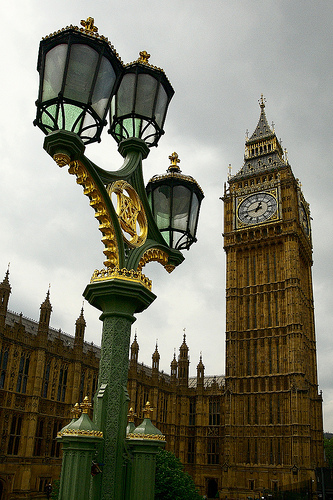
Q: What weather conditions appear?
A: It is overcast.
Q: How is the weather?
A: It is overcast.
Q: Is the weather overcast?
A: Yes, it is overcast.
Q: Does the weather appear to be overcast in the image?
A: Yes, it is overcast.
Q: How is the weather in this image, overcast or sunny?
A: It is overcast.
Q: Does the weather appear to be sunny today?
A: No, it is overcast.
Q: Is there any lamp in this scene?
A: Yes, there is a lamp.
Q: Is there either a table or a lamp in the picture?
A: Yes, there is a lamp.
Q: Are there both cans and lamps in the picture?
A: No, there is a lamp but no cans.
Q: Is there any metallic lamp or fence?
A: Yes, there is a metal lamp.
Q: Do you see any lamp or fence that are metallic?
A: Yes, the lamp is metallic.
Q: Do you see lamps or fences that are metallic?
A: Yes, the lamp is metallic.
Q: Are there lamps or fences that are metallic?
A: Yes, the lamp is metallic.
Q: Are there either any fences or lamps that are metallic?
A: Yes, the lamp is metallic.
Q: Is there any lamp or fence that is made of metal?
A: Yes, the lamp is made of metal.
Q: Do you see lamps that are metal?
A: Yes, there is a metal lamp.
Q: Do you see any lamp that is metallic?
A: Yes, there is a lamp that is metallic.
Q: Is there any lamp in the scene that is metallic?
A: Yes, there is a lamp that is metallic.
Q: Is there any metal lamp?
A: Yes, there is a lamp that is made of metal.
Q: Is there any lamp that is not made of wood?
A: Yes, there is a lamp that is made of metal.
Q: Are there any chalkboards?
A: No, there are no chalkboards.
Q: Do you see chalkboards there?
A: No, there are no chalkboards.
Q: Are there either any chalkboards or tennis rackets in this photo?
A: No, there are no chalkboards or tennis rackets.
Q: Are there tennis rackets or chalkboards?
A: No, there are no chalkboards or tennis rackets.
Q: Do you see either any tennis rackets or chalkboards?
A: No, there are no chalkboards or tennis rackets.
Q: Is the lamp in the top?
A: Yes, the lamp is in the top of the image.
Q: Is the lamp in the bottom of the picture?
A: No, the lamp is in the top of the image.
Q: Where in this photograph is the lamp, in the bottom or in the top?
A: The lamp is in the top of the image.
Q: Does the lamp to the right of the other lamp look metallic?
A: Yes, the lamp is metallic.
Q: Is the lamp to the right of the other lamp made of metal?
A: Yes, the lamp is made of metal.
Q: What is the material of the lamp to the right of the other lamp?
A: The lamp is made of metal.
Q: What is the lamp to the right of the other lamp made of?
A: The lamp is made of metal.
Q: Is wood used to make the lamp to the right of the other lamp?
A: No, the lamp is made of metal.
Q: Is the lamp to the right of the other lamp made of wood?
A: No, the lamp is made of metal.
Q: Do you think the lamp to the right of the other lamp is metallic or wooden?
A: The lamp is metallic.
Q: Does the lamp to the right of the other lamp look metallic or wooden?
A: The lamp is metallic.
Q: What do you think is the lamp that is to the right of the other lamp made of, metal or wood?
A: The lamp is made of metal.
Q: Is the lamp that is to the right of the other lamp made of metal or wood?
A: The lamp is made of metal.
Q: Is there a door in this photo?
A: Yes, there is a door.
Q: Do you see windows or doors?
A: Yes, there is a door.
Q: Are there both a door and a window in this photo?
A: Yes, there are both a door and a window.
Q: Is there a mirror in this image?
A: No, there are no mirrors.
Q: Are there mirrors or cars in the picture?
A: No, there are no mirrors or cars.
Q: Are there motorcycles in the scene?
A: No, there are no motorcycles.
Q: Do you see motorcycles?
A: No, there are no motorcycles.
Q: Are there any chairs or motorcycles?
A: No, there are no motorcycles or chairs.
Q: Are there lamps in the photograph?
A: Yes, there is a lamp.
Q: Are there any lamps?
A: Yes, there is a lamp.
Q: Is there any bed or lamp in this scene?
A: Yes, there is a lamp.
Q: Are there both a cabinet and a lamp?
A: No, there is a lamp but no cabinets.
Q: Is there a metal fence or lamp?
A: Yes, there is a metal lamp.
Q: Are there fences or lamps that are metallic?
A: Yes, the lamp is metallic.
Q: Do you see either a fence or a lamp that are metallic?
A: Yes, the lamp is metallic.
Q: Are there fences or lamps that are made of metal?
A: Yes, the lamp is made of metal.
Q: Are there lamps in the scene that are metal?
A: Yes, there is a metal lamp.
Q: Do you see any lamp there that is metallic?
A: Yes, there is a lamp that is metallic.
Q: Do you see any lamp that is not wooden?
A: Yes, there is a metallic lamp.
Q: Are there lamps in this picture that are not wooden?
A: Yes, there is a metallic lamp.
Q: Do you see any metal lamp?
A: Yes, there is a lamp that is made of metal.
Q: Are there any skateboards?
A: No, there are no skateboards.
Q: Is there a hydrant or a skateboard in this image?
A: No, there are no skateboards or fire hydrants.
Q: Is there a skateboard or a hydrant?
A: No, there are no skateboards or fire hydrants.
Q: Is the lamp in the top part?
A: Yes, the lamp is in the top of the image.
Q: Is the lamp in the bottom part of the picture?
A: No, the lamp is in the top of the image.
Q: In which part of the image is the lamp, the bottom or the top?
A: The lamp is in the top of the image.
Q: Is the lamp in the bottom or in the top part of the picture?
A: The lamp is in the top of the image.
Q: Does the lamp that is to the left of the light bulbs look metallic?
A: Yes, the lamp is metallic.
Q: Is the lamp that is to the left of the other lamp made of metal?
A: Yes, the lamp is made of metal.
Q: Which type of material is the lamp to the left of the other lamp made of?
A: The lamp is made of metal.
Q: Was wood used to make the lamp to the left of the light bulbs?
A: No, the lamp is made of metal.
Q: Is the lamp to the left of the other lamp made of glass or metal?
A: The lamp is made of metal.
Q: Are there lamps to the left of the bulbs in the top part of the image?
A: Yes, there is a lamp to the left of the bulbs.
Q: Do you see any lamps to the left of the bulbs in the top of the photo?
A: Yes, there is a lamp to the left of the bulbs.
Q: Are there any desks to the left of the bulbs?
A: No, there is a lamp to the left of the bulbs.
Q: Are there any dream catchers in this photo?
A: No, there are no dream catchers.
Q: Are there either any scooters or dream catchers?
A: No, there are no dream catchers or scooters.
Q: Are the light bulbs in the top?
A: Yes, the light bulbs are in the top of the image.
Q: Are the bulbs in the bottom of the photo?
A: No, the bulbs are in the top of the image.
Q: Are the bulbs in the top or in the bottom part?
A: The bulbs are in the top of the image.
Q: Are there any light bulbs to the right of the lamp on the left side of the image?
A: Yes, there are light bulbs to the right of the lamp.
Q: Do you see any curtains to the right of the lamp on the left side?
A: No, there are light bulbs to the right of the lamp.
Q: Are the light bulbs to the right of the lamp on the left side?
A: Yes, the light bulbs are to the right of the lamp.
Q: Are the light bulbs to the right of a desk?
A: No, the light bulbs are to the right of the lamp.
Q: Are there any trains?
A: No, there are no trains.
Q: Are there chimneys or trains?
A: No, there are no trains or chimneys.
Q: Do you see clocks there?
A: Yes, there is a clock.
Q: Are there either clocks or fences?
A: Yes, there is a clock.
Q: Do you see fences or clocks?
A: Yes, there is a clock.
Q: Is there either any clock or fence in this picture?
A: Yes, there is a clock.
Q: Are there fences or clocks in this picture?
A: Yes, there is a clock.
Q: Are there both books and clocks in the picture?
A: No, there is a clock but no books.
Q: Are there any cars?
A: No, there are no cars.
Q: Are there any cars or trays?
A: No, there are no cars or trays.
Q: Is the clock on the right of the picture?
A: Yes, the clock is on the right of the image.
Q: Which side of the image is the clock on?
A: The clock is on the right of the image.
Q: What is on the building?
A: The clock is on the building.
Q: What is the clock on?
A: The clock is on the building.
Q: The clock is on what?
A: The clock is on the building.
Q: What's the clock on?
A: The clock is on the building.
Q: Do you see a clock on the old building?
A: Yes, there is a clock on the building.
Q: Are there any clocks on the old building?
A: Yes, there is a clock on the building.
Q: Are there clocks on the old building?
A: Yes, there is a clock on the building.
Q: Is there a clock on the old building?
A: Yes, there is a clock on the building.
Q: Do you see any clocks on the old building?
A: Yes, there is a clock on the building.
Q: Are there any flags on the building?
A: No, there is a clock on the building.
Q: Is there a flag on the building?
A: No, there is a clock on the building.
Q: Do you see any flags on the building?
A: No, there is a clock on the building.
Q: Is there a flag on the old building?
A: No, there is a clock on the building.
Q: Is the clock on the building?
A: Yes, the clock is on the building.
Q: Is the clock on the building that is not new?
A: Yes, the clock is on the building.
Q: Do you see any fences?
A: No, there are no fences.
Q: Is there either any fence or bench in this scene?
A: No, there are no fences or benches.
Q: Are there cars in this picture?
A: No, there are no cars.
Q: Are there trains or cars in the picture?
A: No, there are no cars or trains.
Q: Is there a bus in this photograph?
A: No, there are no buses.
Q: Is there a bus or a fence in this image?
A: No, there are no buses or fences.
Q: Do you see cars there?
A: No, there are no cars.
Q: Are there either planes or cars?
A: No, there are no cars or planes.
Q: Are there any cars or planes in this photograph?
A: No, there are no cars or planes.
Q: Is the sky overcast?
A: Yes, the sky is overcast.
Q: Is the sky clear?
A: No, the sky is overcast.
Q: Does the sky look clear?
A: No, the sky is overcast.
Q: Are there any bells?
A: No, there are no bells.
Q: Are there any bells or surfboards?
A: No, there are no bells or surfboards.